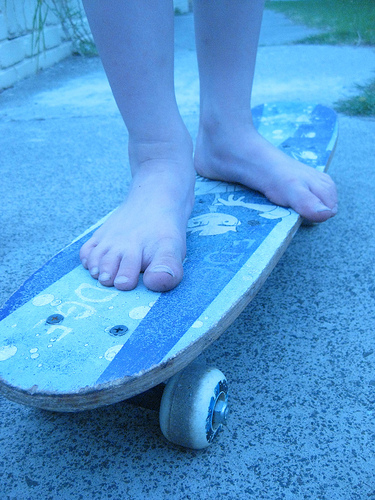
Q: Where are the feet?
A: On the skateboard.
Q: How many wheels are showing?
A: One.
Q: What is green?
A: Grass.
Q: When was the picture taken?
A: Daytime.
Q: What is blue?
A: The overall picture.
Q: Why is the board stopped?
A: The are not moving.